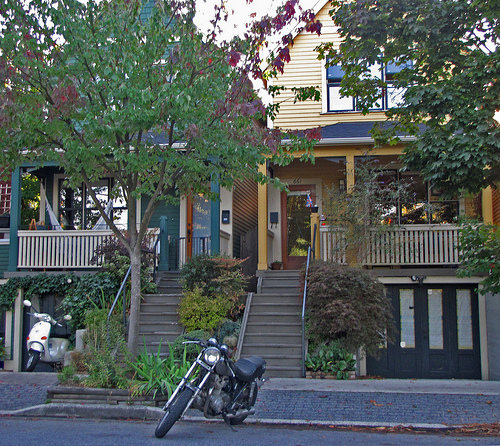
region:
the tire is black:
[166, 408, 178, 424]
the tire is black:
[176, 395, 183, 418]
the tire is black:
[182, 392, 184, 407]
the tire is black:
[162, 386, 177, 427]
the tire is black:
[174, 403, 180, 420]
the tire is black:
[179, 398, 184, 408]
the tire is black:
[170, 385, 180, 416]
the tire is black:
[181, 393, 187, 408]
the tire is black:
[175, 401, 183, 413]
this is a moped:
[10, 285, 85, 387]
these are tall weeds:
[126, 339, 216, 408]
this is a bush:
[303, 250, 398, 372]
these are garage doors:
[351, 262, 496, 384]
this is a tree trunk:
[62, 150, 197, 417]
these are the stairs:
[94, 212, 361, 384]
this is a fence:
[300, 204, 493, 275]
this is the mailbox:
[264, 207, 284, 237]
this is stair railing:
[289, 221, 334, 381]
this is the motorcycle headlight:
[195, 336, 235, 381]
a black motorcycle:
[145, 327, 275, 440]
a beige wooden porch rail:
[318, 215, 480, 270]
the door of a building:
[281, 184, 317, 267]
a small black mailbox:
[267, 208, 279, 230]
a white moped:
[22, 291, 73, 377]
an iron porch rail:
[300, 243, 315, 375]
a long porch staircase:
[237, 269, 305, 379]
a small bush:
[300, 257, 395, 357]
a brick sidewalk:
[0, 370, 498, 437]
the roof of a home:
[266, 119, 484, 136]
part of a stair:
[277, 313, 284, 323]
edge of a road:
[361, 400, 380, 422]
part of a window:
[420, 192, 425, 207]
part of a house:
[319, 109, 337, 133]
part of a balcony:
[52, 160, 72, 242]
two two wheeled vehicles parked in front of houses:
[6, 173, 300, 440]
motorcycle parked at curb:
[143, 310, 278, 442]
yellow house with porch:
[238, 38, 499, 410]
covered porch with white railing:
[250, 136, 492, 277]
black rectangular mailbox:
[268, 203, 280, 233]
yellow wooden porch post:
[252, 143, 274, 275]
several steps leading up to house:
[234, 267, 311, 379]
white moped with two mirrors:
[14, 298, 80, 376]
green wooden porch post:
[9, 162, 21, 269]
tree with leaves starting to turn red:
[3, 34, 333, 360]